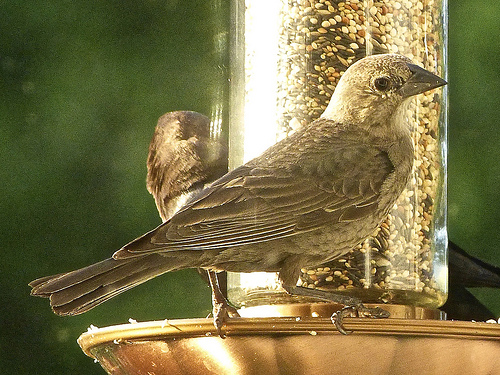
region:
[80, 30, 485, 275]
the bird brown and visible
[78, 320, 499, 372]
copper bird feeder base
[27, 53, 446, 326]
bird standing on feeder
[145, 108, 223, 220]
bird eating seeds at feeder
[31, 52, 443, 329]
brown bird eating feed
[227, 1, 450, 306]
glass top of bird feeder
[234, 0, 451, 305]
bird seed in glass feeder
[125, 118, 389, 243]
wing of brown bird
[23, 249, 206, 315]
tail of brown bird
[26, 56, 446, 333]
bird ready to eat seeds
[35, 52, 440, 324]
bird standing next to seeds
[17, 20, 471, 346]
Two birds on a bird feeder.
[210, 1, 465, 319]
a lot of bird seed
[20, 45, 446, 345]
A little, brown bird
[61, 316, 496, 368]
Gold metallic dish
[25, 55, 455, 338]
Two small brown birds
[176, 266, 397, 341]
tiny, brown bird feet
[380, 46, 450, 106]
small bird's beak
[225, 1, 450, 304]
Glass tube with bird seed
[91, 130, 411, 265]
brown bird's wing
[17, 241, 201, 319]
long brown tail feather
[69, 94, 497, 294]
the bird is standing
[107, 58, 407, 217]
the bird is standing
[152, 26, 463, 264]
the bird is standing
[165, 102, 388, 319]
the bird is brown and visible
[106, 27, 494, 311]
the bird is brown and visible